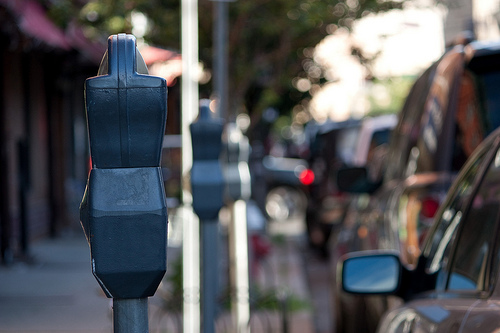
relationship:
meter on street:
[77, 32, 172, 300] [162, 170, 499, 333]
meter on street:
[187, 96, 240, 333] [162, 170, 499, 333]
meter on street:
[184, 92, 269, 331] [235, 166, 498, 329]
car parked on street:
[339, 120, 491, 331] [266, 134, 498, 333]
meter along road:
[77, 32, 172, 300] [291, 29, 498, 331]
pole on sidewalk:
[172, 4, 204, 331] [5, 212, 111, 332]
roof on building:
[6, 9, 102, 59] [2, 54, 224, 277]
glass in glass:
[342, 254, 400, 291] [334, 250, 408, 295]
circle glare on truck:
[300, 169, 314, 185] [258, 119, 361, 251]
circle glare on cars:
[298, 169, 314, 185] [334, 38, 499, 333]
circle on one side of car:
[419, 198, 439, 218] [339, 123, 499, 333]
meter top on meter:
[99, 35, 149, 75] [89, 37, 171, 293]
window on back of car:
[450, 149, 497, 300] [342, 126, 499, 333]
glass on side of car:
[334, 250, 408, 295] [324, 120, 494, 332]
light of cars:
[298, 168, 320, 188] [265, 46, 498, 331]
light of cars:
[419, 198, 438, 218] [265, 46, 498, 331]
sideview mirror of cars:
[335, 159, 382, 199] [293, 50, 498, 333]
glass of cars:
[334, 250, 408, 295] [293, 50, 498, 333]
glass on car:
[334, 250, 408, 295] [339, 120, 491, 331]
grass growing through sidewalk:
[208, 279, 336, 320] [1, 212, 212, 333]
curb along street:
[263, 244, 323, 332] [297, 217, 347, 331]